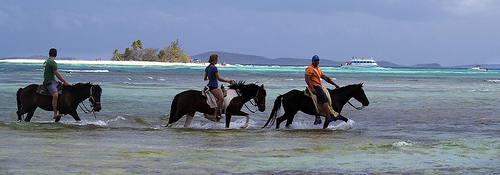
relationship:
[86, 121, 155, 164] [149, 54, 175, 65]
water near shore line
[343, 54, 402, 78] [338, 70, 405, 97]
boat out in ocean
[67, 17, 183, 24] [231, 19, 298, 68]
partially cloudy sky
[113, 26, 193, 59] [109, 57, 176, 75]
trees and beach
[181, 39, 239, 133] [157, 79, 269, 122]
woman riding horse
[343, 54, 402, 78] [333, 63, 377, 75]
boat on waves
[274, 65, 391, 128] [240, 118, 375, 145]
horses in shallow water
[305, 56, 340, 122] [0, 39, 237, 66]
people enjoying island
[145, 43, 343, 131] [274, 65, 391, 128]
people on horses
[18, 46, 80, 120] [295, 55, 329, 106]
man in orange shirt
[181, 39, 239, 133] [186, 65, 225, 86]
woman in blue shirt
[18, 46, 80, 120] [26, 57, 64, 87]
man in green shirt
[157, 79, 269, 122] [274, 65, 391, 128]
horse behind other horses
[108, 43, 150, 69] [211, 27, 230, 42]
green bush in background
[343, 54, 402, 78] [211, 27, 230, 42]
boat in background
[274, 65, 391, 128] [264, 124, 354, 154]
horses walking in water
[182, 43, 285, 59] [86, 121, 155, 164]
mountains behind water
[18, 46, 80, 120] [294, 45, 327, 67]
man in blue baseball cap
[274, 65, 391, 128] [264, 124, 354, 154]
black horse in water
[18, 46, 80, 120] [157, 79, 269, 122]
man riding horse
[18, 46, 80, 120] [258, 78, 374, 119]
man riding horse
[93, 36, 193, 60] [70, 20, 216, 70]
small distance island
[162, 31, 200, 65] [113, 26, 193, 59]
range of trees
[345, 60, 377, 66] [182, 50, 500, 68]
boat in distance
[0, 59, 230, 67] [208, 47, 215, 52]
beach in distance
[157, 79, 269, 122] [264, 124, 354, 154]
horse walking in water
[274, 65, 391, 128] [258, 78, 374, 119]
horses tail black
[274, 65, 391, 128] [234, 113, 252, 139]
horses leg white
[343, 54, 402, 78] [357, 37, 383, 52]
boat in back ground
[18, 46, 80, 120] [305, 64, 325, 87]
man wearing orange shirt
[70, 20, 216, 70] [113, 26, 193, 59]
island of trees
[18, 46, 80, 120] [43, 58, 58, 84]
man wearing green shirt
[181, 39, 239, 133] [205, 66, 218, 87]
woman wearing blue shirt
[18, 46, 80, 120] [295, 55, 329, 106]
man wearing orange shirt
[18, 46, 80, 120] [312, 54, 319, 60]
man wearing baseball cap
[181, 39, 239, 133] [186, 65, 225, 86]
woman wearing a blue shirt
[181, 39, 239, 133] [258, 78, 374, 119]
woman riding a horse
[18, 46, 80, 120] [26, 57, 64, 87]
man wearing green shirt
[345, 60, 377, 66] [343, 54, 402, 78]
boat white boat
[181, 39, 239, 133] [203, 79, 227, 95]
woman wearing short shorts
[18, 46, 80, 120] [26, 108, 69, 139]
man wearing sandals